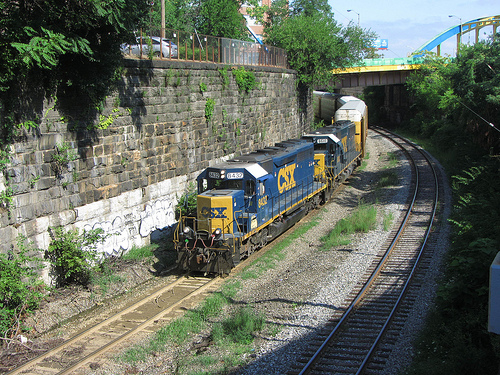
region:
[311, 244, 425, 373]
The railroad track is brown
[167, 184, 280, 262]
the train is yellow and blue.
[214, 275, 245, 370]
There is green grass in the rocks.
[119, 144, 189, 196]
the wall is made out of rocks.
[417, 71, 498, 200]
the trees is green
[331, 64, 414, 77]
there is a bridge up there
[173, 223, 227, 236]
the train has two lights in front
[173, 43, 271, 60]
A fence is at the the top ,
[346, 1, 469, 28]
there are two light poles.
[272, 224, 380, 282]
the gravel is grey in color.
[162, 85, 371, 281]
The train is on the track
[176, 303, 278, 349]
The patch of grass is green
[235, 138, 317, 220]
The color of the train is blue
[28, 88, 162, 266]
The wall is made of brick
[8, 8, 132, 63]
The tree is the color green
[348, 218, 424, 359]
The train tracks on the ground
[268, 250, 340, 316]
The gravel on the ground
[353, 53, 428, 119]
The bridge is made of concrete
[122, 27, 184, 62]
A car is parked on the street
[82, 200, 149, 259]
The graffiti on the wall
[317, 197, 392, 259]
weeds between the tracks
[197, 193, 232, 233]
yellow nose of an engine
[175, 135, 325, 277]
blue and yellow engine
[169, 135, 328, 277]
yellow and blue engine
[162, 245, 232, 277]
cattle guard on an engine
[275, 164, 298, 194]
a csx logo on the engine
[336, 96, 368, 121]
white roof of a train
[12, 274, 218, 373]
railroad track in front of train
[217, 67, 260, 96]
plants growing on a wall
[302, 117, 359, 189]
second engine on the train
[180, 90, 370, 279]
a long colorful train on the track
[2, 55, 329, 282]
a brick wall next to the track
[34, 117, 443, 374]
the train tracks on the ground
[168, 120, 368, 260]
the engines on the train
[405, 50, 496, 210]
the green leafy trees by the track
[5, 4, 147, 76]
another green leafy tree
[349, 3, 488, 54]
the blue sky above everything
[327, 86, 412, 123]
a little tunnel for the bridge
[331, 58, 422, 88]
a bridge next to the wall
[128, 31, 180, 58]
a car parked next to the pole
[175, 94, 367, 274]
A long rail train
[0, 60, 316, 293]
A long and tall brick wall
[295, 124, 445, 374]
A section of railroad track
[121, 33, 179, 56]
A parked white car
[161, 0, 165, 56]
A thin tall wooden pole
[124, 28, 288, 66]
A length of metal fencing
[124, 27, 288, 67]
A fenced in barrier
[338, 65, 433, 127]
A partial section of a train tunnel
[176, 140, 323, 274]
A blue train engine car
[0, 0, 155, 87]
A large over hanging tree